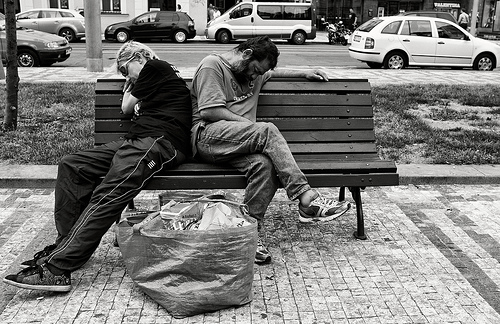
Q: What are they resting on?
A: Bench.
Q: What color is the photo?
A: Black and white.